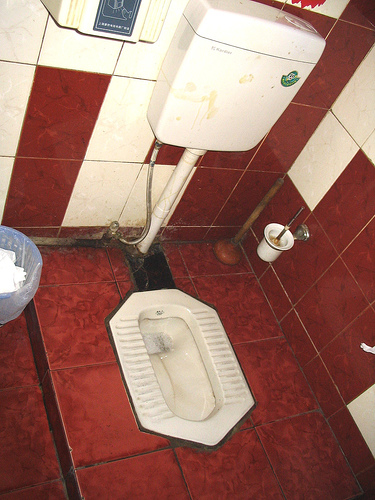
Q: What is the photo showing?
A: It is showing a bathroom.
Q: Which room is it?
A: It is a bathroom.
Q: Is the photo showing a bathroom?
A: Yes, it is showing a bathroom.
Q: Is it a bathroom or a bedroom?
A: It is a bathroom.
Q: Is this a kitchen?
A: No, it is a bathroom.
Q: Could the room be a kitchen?
A: No, it is a bathroom.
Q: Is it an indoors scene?
A: Yes, it is indoors.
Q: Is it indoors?
A: Yes, it is indoors.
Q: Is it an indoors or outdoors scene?
A: It is indoors.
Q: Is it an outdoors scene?
A: No, it is indoors.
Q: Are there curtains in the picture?
A: No, there are no curtains.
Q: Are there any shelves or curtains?
A: No, there are no curtains or shelves.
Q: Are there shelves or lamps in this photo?
A: No, there are no shelves or lamps.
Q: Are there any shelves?
A: No, there are no shelves.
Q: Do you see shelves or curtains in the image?
A: No, there are no shelves or curtains.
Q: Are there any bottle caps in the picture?
A: No, there are no bottle caps.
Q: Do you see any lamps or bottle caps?
A: No, there are no bottle caps or lamps.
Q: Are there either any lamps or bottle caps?
A: No, there are no bottle caps or lamps.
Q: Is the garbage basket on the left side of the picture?
A: Yes, the garbage basket is on the left of the image.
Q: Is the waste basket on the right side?
A: No, the waste basket is on the left of the image.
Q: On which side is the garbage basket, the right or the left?
A: The garbage basket is on the left of the image.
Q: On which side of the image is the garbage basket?
A: The garbage basket is on the left of the image.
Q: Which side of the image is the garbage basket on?
A: The garbage basket is on the left of the image.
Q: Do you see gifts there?
A: No, there are no gifts.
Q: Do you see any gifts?
A: No, there are no gifts.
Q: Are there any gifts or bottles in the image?
A: No, there are no gifts or bottles.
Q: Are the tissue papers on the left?
A: Yes, the tissue papers are on the left of the image.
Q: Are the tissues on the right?
A: No, the tissues are on the left of the image.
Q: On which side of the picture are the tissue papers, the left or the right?
A: The tissue papers are on the left of the image.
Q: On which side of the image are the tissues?
A: The tissues are on the left of the image.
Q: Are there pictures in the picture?
A: No, there are no pictures.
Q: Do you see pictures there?
A: No, there are no pictures.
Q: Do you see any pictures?
A: No, there are no pictures.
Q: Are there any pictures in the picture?
A: No, there are no pictures.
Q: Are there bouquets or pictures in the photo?
A: No, there are no pictures or bouquets.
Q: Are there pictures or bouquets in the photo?
A: No, there are no pictures or bouquets.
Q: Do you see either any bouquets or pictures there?
A: No, there are no pictures or bouquets.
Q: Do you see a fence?
A: No, there are no fences.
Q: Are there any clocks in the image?
A: No, there are no clocks.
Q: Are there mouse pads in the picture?
A: No, there are no mouse pads.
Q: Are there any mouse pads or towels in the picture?
A: No, there are no mouse pads or towels.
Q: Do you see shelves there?
A: No, there are no shelves.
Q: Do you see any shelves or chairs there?
A: No, there are no shelves or chairs.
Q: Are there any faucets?
A: No, there are no faucets.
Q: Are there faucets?
A: No, there are no faucets.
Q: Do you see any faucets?
A: No, there are no faucets.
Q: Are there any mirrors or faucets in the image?
A: No, there are no faucets or mirrors.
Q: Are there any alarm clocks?
A: No, there are no alarm clocks.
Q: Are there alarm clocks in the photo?
A: No, there are no alarm clocks.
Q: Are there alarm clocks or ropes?
A: No, there are no alarm clocks or ropes.